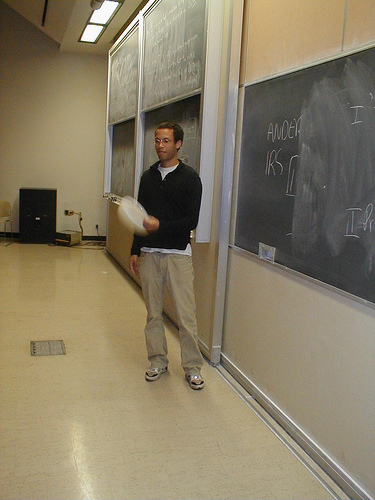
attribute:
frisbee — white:
[107, 191, 154, 239]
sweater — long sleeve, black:
[114, 158, 212, 257]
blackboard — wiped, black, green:
[233, 43, 373, 303]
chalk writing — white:
[251, 96, 374, 239]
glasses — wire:
[148, 133, 178, 150]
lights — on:
[68, 1, 124, 52]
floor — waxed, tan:
[3, 236, 131, 496]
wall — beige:
[1, 53, 100, 242]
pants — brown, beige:
[130, 245, 207, 369]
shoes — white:
[136, 358, 215, 399]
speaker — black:
[87, 216, 106, 244]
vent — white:
[31, 333, 70, 361]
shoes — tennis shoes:
[144, 360, 205, 389]